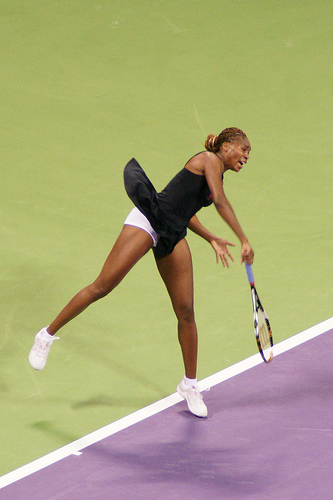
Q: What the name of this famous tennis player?
A: Serena Williams.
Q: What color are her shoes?
A: White.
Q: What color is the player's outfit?
A: Black and white.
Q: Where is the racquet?
A: In the player's hand.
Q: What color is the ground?
A: Purple, green, and white.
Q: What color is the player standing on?
A: Purple.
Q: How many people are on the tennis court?
A: 1.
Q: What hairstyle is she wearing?
A: Braids wrapped into a bun.